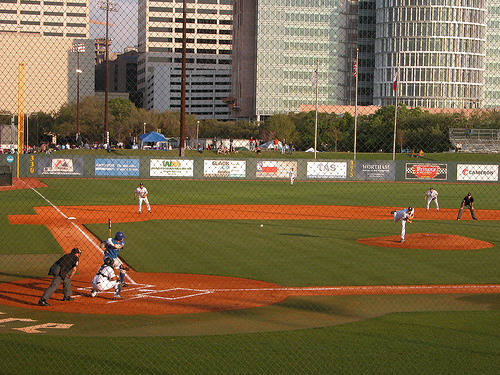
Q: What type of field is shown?
A: A baseball field.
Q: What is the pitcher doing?
A: Throwing a pitch.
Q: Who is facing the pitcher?
A: The batter.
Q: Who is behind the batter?
A: The catcher.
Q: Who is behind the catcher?
A: The umpire.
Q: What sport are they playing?
A: Baseball.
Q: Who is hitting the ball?
A: Batter.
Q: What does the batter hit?
A: Baseball.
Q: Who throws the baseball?
A: Pitcher.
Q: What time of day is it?
A: Daytime.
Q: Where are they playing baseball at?
A: City.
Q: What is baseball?
A: A sport.